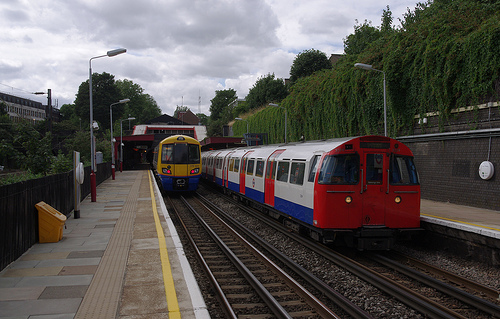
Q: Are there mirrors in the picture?
A: No, there are no mirrors.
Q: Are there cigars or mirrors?
A: No, there are no mirrors or cigars.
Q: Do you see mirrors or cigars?
A: No, there are no mirrors or cigars.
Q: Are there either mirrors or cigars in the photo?
A: No, there are no mirrors or cigars.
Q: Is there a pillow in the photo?
A: No, there are no pillows.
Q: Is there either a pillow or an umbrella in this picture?
A: No, there are no pillows or umbrellas.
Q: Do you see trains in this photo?
A: Yes, there is a train.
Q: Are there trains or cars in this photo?
A: Yes, there is a train.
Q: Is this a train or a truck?
A: This is a train.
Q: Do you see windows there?
A: Yes, there is a window.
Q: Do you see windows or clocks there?
A: Yes, there is a window.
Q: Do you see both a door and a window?
A: Yes, there are both a window and a door.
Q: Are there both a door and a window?
A: Yes, there are both a window and a door.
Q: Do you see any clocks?
A: No, there are no clocks.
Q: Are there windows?
A: Yes, there is a window.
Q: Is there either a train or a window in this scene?
A: Yes, there is a window.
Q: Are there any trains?
A: Yes, there is a train.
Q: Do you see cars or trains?
A: Yes, there is a train.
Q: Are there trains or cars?
A: Yes, there is a train.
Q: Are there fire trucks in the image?
A: No, there are no fire trucks.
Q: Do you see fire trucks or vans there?
A: No, there are no fire trucks or vans.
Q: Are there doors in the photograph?
A: Yes, there is a door.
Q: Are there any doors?
A: Yes, there is a door.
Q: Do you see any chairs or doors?
A: Yes, there is a door.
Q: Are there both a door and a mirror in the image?
A: No, there is a door but no mirrors.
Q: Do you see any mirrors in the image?
A: No, there are no mirrors.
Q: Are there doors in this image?
A: Yes, there is a door.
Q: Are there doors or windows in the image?
A: Yes, there is a door.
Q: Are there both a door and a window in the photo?
A: Yes, there are both a door and a window.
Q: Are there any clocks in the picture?
A: No, there are no clocks.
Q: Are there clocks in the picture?
A: No, there are no clocks.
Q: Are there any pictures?
A: No, there are no pictures.